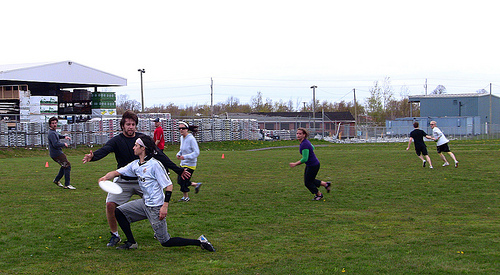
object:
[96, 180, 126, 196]
frisbee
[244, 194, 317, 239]
grass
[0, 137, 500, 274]
field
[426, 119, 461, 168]
man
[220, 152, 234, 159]
cone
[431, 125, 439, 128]
beard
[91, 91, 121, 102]
crate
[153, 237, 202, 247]
socks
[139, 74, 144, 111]
pole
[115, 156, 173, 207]
shirt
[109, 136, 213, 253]
man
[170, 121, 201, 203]
woman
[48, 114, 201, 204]
lot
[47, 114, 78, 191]
players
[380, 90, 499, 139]
building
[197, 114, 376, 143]
fence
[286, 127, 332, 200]
people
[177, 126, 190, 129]
sunglasses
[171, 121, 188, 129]
headband